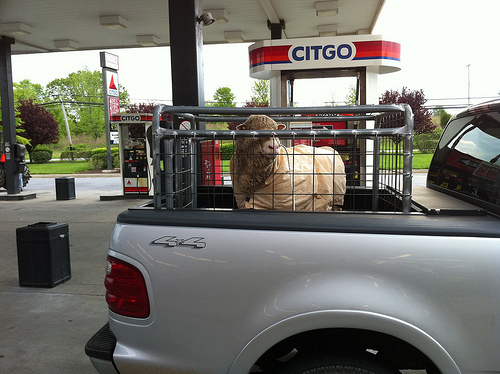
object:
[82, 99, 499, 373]
pickup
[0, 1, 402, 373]
gas station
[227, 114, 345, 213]
sheep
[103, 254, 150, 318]
taillight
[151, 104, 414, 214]
cage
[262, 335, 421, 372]
wheel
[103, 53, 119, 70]
board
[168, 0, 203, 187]
column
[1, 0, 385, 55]
roof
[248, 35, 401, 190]
gas pump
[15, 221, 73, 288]
trash can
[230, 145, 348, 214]
blanket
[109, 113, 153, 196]
gas pump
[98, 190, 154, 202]
island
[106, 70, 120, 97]
sign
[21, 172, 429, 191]
road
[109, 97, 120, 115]
price sign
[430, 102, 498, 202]
window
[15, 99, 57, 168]
tree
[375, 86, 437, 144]
tree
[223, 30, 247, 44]
light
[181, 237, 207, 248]
number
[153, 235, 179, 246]
number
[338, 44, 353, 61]
letter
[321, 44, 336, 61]
letter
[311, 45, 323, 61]
letter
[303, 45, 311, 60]
letter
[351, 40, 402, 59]
lines